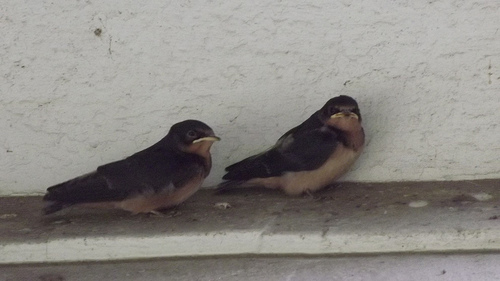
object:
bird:
[213, 94, 366, 197]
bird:
[40, 119, 221, 218]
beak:
[185, 127, 222, 145]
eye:
[187, 129, 197, 139]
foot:
[147, 205, 173, 219]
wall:
[410, 24, 495, 153]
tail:
[42, 164, 107, 216]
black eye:
[332, 105, 340, 112]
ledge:
[1, 167, 494, 279]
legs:
[148, 206, 168, 222]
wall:
[48, 9, 160, 131]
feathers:
[280, 132, 296, 150]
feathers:
[227, 168, 245, 193]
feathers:
[338, 95, 357, 104]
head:
[321, 95, 362, 133]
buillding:
[0, 0, 500, 281]